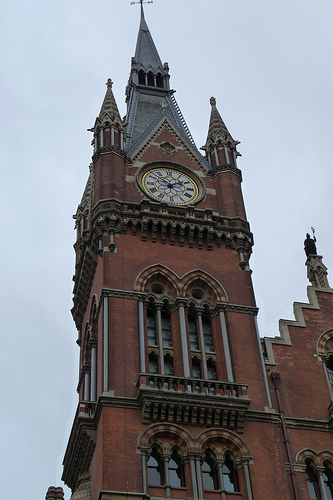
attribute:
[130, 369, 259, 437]
balcony — small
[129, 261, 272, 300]
arches — striped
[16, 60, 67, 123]
clouds — white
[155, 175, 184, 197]
flower design — black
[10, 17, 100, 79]
sky — blue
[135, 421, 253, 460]
awning — ornately-carved, arched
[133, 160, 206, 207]
clock — large,   large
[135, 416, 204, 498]
window — arched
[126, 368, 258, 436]
railing — stone, carved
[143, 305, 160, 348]
window — large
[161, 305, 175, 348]
window — large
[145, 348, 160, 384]
window — large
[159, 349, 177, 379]
window — large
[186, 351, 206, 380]
window — large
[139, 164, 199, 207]
clock — white, roman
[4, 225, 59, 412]
sky — foggy 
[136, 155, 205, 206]
clock — black, white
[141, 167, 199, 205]
clock — large, white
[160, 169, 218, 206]
face — white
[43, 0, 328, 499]
tower — brick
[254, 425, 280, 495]
bricks — red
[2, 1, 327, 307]
sky — blue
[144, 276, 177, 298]
window —  circular 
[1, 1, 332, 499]
sky — blue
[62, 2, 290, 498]
clock tower — ornate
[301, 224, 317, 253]
statued — black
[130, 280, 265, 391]
window — arched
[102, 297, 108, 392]
column — gray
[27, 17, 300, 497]
building — large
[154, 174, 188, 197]
circle — golden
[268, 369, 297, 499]
pipe —  rusty, metal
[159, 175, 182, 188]
dials — black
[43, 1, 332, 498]
building — dark red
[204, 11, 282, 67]
clouds — white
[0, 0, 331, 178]
sky — blue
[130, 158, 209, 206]
rim — golden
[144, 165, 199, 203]
accents — gold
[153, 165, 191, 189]
numerals — black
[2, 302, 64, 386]
clouds — white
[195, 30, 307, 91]
clouds — white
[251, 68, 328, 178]
clouds — white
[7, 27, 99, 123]
clouds — white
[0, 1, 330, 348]
sky — blue